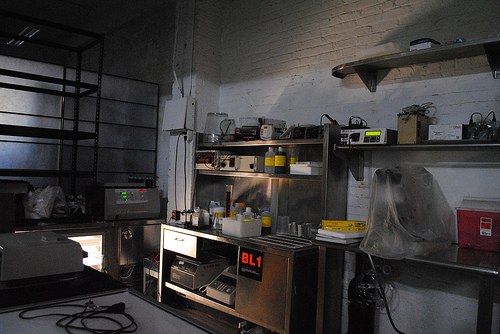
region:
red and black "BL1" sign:
[228, 238, 293, 288]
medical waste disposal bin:
[443, 182, 498, 272]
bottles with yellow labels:
[256, 140, 291, 183]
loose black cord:
[10, 279, 235, 332]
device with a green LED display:
[328, 108, 391, 163]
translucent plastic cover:
[334, 146, 463, 293]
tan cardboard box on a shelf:
[376, 92, 448, 152]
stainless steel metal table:
[310, 203, 499, 327]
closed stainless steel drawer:
[149, 219, 213, 272]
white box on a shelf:
[416, 111, 482, 146]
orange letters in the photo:
[233, 245, 274, 277]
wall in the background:
[271, 70, 317, 114]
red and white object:
[456, 201, 498, 238]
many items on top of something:
[188, 190, 278, 238]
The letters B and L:
[233, 251, 263, 275]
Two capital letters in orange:
[229, 249, 256, 271]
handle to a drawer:
[156, 233, 199, 256]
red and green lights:
[103, 186, 150, 212]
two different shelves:
[350, 26, 465, 173]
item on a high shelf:
[398, 27, 443, 72]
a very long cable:
[55, 277, 145, 330]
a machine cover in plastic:
[350, 151, 450, 262]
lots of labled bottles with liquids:
[175, 141, 305, 231]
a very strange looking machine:
[77, 167, 162, 227]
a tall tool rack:
[0, 23, 122, 220]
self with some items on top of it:
[320, 45, 496, 87]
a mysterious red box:
[452, 176, 498, 265]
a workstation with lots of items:
[155, 119, 327, 318]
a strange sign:
[230, 240, 280, 292]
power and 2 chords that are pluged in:
[160, 56, 199, 209]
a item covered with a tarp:
[357, 161, 466, 259]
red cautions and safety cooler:
[451, 196, 498, 236]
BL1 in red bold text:
[235, 254, 274, 276]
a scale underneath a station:
[171, 255, 205, 280]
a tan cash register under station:
[203, 267, 254, 305]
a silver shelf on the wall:
[322, 31, 497, 88]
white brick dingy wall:
[253, 27, 336, 80]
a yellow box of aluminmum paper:
[326, 214, 357, 234]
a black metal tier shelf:
[34, 26, 128, 185]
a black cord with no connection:
[72, 295, 129, 329]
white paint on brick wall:
[270, 25, 325, 86]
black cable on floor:
[61, 293, 133, 330]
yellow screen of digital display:
[356, 126, 386, 139]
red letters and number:
[237, 248, 266, 270]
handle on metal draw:
[166, 233, 192, 246]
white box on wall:
[155, 89, 202, 139]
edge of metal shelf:
[244, 130, 320, 151]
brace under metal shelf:
[345, 60, 390, 96]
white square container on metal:
[214, 214, 264, 244]